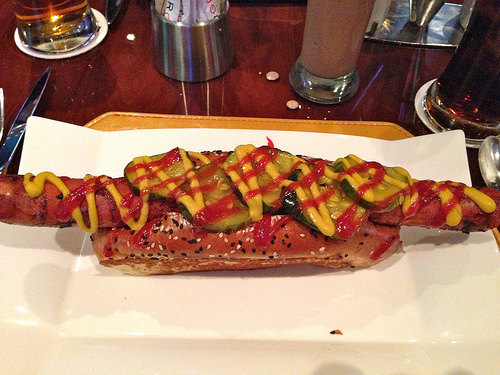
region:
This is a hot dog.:
[38, 132, 469, 311]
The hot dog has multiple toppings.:
[37, 88, 454, 309]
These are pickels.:
[133, 146, 403, 225]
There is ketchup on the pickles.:
[128, 155, 382, 239]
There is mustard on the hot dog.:
[28, 160, 498, 207]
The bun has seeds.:
[121, 224, 356, 272]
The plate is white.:
[85, 303, 441, 373]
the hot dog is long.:
[27, 97, 470, 291]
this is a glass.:
[295, 4, 359, 114]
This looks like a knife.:
[13, 58, 50, 193]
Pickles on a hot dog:
[123, 155, 408, 230]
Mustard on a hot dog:
[24, 173, 53, 197]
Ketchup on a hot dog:
[57, 200, 72, 220]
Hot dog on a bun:
[0, 173, 499, 235]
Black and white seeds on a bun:
[91, 210, 398, 268]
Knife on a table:
[1, 63, 53, 182]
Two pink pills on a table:
[262, 65, 299, 111]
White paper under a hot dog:
[3, 112, 498, 372]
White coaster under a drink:
[13, 8, 110, 57]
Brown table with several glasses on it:
[1, 0, 498, 134]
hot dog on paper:
[32, 166, 475, 263]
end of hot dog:
[0, 188, 89, 243]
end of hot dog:
[408, 175, 498, 242]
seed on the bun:
[285, 240, 295, 255]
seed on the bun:
[223, 246, 235, 259]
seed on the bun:
[145, 245, 162, 254]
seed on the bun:
[351, 238, 368, 255]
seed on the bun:
[222, 238, 237, 245]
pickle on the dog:
[193, 168, 272, 238]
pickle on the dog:
[337, 163, 398, 208]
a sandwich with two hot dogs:
[0, 142, 499, 279]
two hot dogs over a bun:
[0, 142, 499, 275]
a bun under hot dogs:
[80, 218, 405, 278]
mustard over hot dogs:
[20, 140, 495, 244]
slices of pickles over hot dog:
[127, 143, 418, 235]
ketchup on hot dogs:
[44, 135, 476, 242]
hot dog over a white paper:
[6, 107, 476, 374]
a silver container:
[141, 3, 243, 88]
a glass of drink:
[6, 4, 106, 61]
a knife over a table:
[3, 58, 57, 177]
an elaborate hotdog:
[3, 120, 491, 287]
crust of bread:
[90, 250, 360, 275]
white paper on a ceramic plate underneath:
[16, 100, 222, 141]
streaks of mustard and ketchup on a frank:
[25, 165, 130, 221]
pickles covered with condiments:
[235, 145, 375, 212]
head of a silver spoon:
[475, 130, 495, 190]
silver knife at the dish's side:
[6, 60, 51, 167]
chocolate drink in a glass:
[281, 2, 372, 98]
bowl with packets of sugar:
[135, 0, 246, 90]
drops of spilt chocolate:
[255, 65, 300, 110]